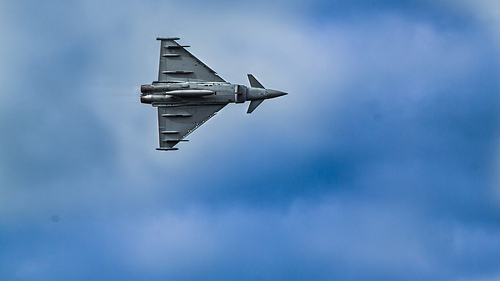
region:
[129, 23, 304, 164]
plane in the sky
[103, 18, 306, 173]
airplane flying near the clouds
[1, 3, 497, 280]
white clouds in the sky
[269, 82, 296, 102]
sharp point on the tip of the plane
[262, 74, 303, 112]
nose of the plane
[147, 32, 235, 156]
wings make a triangle shape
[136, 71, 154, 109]
tail of the plane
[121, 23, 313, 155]
light gray airplane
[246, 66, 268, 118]
two small wings on either side of the plane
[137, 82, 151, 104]
engines on the back of the plane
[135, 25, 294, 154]
military plane view from below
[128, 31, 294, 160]
flying military plane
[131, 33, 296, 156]
underbelly of military plane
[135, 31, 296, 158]
military plane flying in the clouds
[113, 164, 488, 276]
blue sky with clouds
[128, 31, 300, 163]
plane flying across the sky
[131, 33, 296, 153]
plane flying in the clouds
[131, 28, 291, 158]
view of plane from the ground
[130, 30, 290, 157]
view of military plane from the ground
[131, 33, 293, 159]
military plane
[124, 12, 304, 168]
dark gray airplane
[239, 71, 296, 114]
nose of the plane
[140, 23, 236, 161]
wings of the plane make a triangle shape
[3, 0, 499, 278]
dark blue sky covered in clouds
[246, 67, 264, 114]
two small wings on the plane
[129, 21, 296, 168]
plane flying through the clouds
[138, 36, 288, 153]
Plane in the sky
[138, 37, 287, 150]
The plane is flying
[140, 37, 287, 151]
A jet in the air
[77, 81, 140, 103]
Fire coming from engines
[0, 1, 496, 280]
Sky has some clouds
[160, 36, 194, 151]
Hardpoints have no weapons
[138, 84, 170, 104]
Jet has two engines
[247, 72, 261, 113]
Little wings near front of jet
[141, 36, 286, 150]
The jet is gray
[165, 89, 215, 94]
Fuel tank on jet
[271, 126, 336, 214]
part of a cloud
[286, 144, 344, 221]
par of a cloud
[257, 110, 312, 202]
part of a cloud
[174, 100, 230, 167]
edge of a wing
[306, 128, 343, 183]
part of a cloud